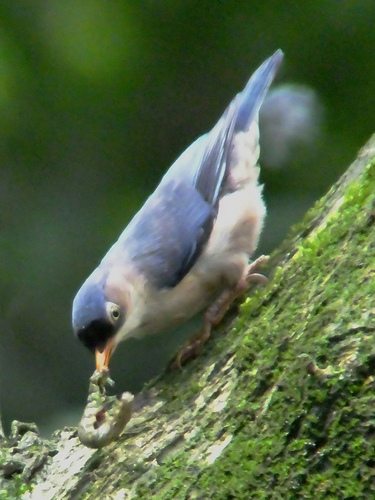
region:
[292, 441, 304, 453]
part of the grass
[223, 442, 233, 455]
part of a surface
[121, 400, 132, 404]
part of a cocktail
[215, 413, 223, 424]
part of a wheel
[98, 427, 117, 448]
part of a tail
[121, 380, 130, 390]
edge of a tail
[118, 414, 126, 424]
side of a tail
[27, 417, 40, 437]
part of a surface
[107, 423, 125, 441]
part of a tail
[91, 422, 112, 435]
edge of a tail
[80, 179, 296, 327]
Bird is sitting in branch.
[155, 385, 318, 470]
Branch is green and brown color.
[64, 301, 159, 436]
Bird is holding worms in mouth.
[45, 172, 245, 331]
Bird is grey color.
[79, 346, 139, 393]
Beak is orange color.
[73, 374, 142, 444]
Worm is green color.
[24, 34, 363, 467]
Day time picture.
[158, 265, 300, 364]
Legs are red color.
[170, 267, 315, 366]
two legs for bird.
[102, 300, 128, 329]
Eyes are white and black color.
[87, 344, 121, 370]
beak of the bird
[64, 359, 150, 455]
animal in front of bird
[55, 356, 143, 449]
worm caught by the bird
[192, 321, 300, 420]
yellow and white surface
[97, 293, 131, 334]
eye of the bird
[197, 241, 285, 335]
feet of the bird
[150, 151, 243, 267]
feather of the bird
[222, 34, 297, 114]
tail feathers of the bird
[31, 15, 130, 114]
blurry background of photo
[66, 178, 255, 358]
dark and light bird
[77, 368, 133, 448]
green worm in bird's mouth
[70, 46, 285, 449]
blue bird trying to eat a green worm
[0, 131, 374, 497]
tree log with blue bird on it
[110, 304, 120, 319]
green and black bird's eye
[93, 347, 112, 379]
bird's beak holding green worm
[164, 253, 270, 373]
blue bird's feet clutching tree trunk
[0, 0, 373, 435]
fuzzy green background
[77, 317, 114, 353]
black spot on white and blue bird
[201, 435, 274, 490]
green moss on tree trunk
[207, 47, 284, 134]
blue bird's tail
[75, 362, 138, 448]
Caterpillar in the birds beak.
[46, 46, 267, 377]
Bird on the tree.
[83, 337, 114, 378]
Orange beak on the bird.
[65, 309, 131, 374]
Black coloring above bird's beak.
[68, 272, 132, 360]
Blue head on the bird.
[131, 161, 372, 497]
Green moss on the tree.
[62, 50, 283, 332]
Blue feathers on the bird.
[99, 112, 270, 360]
White feathers on the underside of the bird.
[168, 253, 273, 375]
Creamed color feet on the bird.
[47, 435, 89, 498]
Gray bark on the tree.